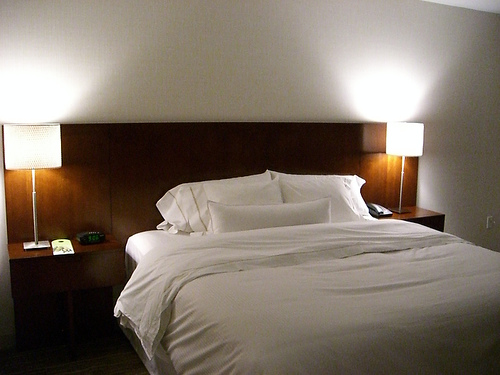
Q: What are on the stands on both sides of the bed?
A: Lamps.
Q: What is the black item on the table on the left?
A: Clock.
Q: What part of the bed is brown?
A: Headboard.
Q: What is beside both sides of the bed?
A: Nightstands.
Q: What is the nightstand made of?
A: Wood.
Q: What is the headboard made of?
A: Wood.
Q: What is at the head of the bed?
A: Pillows.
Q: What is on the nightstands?
A: Lamps.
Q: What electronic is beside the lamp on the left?
A: A phone.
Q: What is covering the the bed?
A: Blankets.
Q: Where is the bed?
A: In a room.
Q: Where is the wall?
A: Behind the bed.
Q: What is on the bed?
A: Pillows.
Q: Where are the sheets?
A: On the bed.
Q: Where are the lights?
A: Next to the bed.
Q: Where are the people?
A: None in photo.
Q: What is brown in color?
A: The headboard.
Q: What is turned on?
A: The lamp.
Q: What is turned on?
A: Both lamps.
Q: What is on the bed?
A: Pillows.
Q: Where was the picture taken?
A: In a bedroom.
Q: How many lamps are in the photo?
A: Two.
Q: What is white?
A: Bed sheets.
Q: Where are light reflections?
A: On the wall.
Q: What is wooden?
A: The headboard.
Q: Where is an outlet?
A: On the wall.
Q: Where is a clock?
A: On the side table.